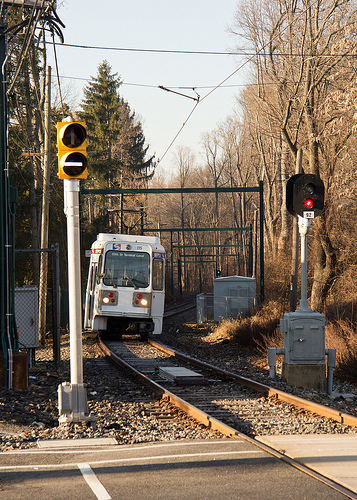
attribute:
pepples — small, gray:
[21, 386, 58, 426]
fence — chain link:
[193, 289, 259, 324]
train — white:
[77, 231, 165, 337]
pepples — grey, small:
[134, 418, 156, 437]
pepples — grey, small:
[251, 353, 279, 381]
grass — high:
[229, 308, 355, 387]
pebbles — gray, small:
[37, 421, 125, 436]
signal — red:
[271, 168, 322, 216]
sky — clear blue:
[89, 5, 212, 43]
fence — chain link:
[12, 245, 61, 378]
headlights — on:
[92, 287, 154, 313]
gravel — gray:
[115, 384, 184, 437]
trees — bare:
[297, 69, 353, 168]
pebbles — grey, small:
[87, 419, 125, 436]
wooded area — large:
[3, 1, 356, 264]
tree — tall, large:
[83, 79, 131, 146]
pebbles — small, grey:
[109, 410, 151, 436]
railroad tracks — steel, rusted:
[93, 298, 356, 498]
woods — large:
[0, 0, 355, 312]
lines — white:
[76, 464, 111, 499]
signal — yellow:
[52, 118, 95, 180]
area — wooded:
[64, 90, 356, 383]